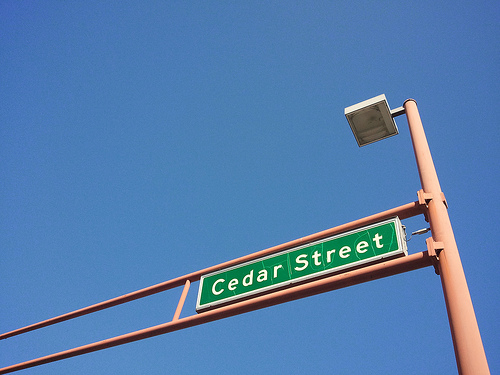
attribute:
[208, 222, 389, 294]
cedar street — lower case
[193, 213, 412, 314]
sign — green, white, name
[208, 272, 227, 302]
c — white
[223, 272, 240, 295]
e — white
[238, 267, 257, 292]
d — white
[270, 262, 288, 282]
r — white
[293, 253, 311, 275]
s — white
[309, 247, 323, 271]
t — white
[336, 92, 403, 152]
light — rectangular, white, off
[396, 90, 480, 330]
post — red, metal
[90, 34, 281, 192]
sky — blue, clear